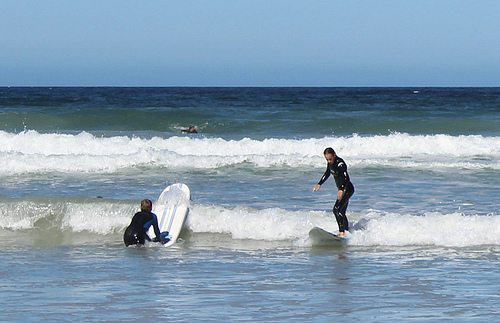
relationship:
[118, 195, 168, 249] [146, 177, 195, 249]
man getting on surfboard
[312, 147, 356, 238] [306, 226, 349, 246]
surfers riding surfboard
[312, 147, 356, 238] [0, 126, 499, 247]
surfers ride wave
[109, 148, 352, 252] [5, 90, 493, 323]
surfers in ocean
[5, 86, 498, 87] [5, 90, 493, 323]
horizon line by ocean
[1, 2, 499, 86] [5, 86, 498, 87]
sky above horizon line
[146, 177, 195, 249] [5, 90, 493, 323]
surfboard into ocean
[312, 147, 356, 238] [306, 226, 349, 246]
surfers on surfboard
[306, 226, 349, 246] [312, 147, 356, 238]
surfboard with surfers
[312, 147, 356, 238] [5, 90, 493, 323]
surfers in ocean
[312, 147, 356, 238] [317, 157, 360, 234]
surfers has wet suit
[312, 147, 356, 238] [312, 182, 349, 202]
surfers has hands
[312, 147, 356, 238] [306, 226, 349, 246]
surfers pulling surfboard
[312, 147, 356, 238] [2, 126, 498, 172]
surfers on wave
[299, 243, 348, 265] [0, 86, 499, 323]
reflection on ocean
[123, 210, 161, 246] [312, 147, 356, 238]
wet suit of surfers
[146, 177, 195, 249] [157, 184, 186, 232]
surfboard with stripes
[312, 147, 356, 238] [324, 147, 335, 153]
surfers has hair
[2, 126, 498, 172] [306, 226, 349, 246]
wave onto surfboard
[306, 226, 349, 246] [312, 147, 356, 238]
surfboard under surfers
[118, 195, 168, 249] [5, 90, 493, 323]
man into ocean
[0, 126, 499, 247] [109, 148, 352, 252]
wave next to surfers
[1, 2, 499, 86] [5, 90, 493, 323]
sky above ocean